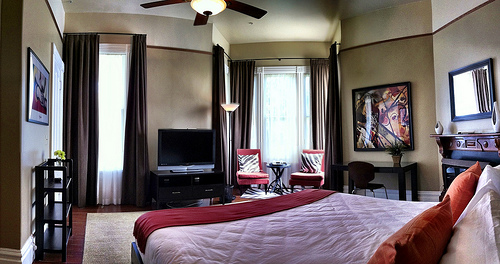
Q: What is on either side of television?
A: Windows.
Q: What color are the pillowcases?
A: Rust colored.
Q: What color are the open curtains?
A: Dark gray.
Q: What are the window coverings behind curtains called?
A: Sheers.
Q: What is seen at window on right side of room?
A: Table and two chairs.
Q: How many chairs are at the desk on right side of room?
A: One.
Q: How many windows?
A: 2.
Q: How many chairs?
A: 3.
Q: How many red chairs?
A: 2.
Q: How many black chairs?
A: 1.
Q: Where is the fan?
A: Ceiling.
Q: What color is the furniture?
A: Black.